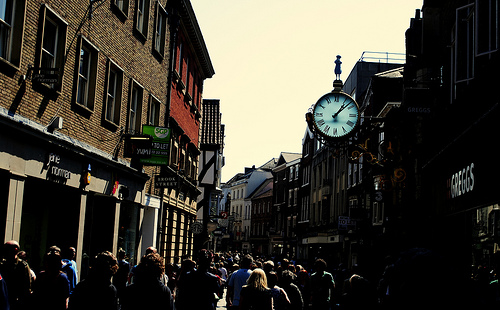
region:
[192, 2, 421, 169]
light in daytime sky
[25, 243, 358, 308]
crowd walking on street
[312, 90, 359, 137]
white face of clock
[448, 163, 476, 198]
sign on front of building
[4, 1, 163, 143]
windows on brick wall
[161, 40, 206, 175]
red wall of building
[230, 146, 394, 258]
front of buildings along street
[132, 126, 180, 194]
signs on front of building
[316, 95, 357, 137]
roman numerals on clock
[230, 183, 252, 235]
face of white building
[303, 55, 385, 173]
A large ornate clock.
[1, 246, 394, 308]
A crowd of people.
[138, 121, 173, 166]
A black and green sign.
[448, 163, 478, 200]
Some white colored letters.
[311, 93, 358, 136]
Black and white clock face.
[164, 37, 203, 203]
A red brick wall.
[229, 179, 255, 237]
A cream colored building.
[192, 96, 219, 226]
A white and brown building.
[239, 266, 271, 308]
A person with blonde hair.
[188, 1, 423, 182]
A bright white sky.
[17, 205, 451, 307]
several people walking between buildings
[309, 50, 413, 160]
a clock on the side of a building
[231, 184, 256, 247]
the facade of a building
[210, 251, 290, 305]
a crowd of people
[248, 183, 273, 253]
the facade of a building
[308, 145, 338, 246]
the facade of a building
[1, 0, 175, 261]
the facade of a building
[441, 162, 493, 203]
a sign reading Greggs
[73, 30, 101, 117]
a window on a building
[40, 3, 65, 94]
a window on a building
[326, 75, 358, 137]
This clock is a very detailed timepiece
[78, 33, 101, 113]
There is a window that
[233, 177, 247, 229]
There is a white building here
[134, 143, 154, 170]
There is this a brand that is YUMI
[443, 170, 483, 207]
This is the name that is GREGGS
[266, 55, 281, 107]
There is a light white sky here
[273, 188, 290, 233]
There is a dark brown brick building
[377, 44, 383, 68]
There is a silver gate that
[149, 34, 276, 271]
Jackson Mingus took this photo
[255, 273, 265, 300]
This person has a head of blond hair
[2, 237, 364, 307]
A crowd of people on the street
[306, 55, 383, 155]
A clock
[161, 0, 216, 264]
A building with red wall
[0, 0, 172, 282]
A building with brown wall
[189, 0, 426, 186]
A creamy colored sky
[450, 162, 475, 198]
A store sign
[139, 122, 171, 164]
A green and black store sign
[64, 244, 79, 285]
A person in a blue shirt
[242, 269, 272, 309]
A person with blond hair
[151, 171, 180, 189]
A black and white sign